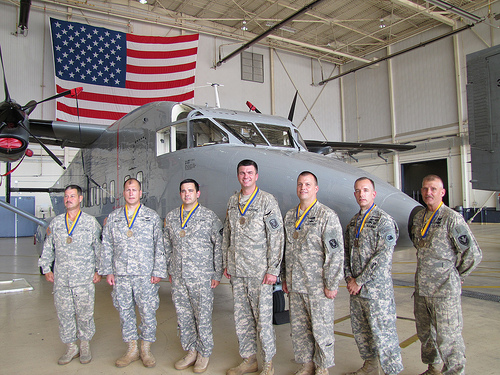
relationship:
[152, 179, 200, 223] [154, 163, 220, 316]
medal around soldier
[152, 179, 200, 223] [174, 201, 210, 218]
medal around neck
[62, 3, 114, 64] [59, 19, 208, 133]
stars on flag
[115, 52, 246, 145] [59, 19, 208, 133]
stripes on flag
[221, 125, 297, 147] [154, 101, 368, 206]
windshield on plane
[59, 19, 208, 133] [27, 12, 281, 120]
flag on wall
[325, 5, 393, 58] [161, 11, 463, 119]
beams on ceiling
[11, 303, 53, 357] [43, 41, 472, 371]
floor of building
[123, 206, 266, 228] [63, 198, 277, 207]
medals around necks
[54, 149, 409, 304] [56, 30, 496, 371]
soldiers in hanger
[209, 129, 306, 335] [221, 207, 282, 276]
man in uniform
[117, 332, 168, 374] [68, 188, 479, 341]
boots on men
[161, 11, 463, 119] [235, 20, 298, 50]
ceiling with light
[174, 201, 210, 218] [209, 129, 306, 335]
neck on man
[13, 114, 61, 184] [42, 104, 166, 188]
propeller on right